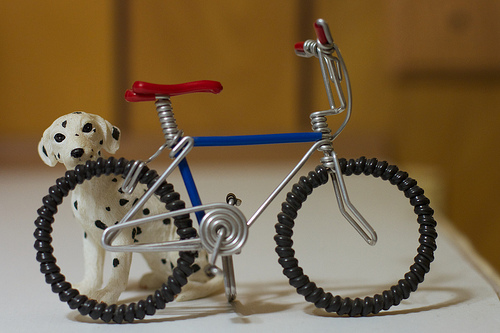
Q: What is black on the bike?
A: The wheels.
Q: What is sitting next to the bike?
A: A dalmatian.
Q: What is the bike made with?
A: Paper clips.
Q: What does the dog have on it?
A: Black spots.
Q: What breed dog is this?
A: Dalmatian.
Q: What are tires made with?
A: Phone cord.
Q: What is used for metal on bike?
A: Paper clips.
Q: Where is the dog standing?
A: Behind bike.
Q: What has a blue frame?
A: A bike.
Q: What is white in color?
A: Table.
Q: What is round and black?
A: Tires.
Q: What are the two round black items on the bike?
A: Tires.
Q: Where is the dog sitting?
A: On the table by the back wheel of the bike.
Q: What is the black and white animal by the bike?
A: A dog.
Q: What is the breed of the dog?
A: Dalmatian.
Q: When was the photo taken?
A: Daytime.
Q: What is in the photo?
A: A bike.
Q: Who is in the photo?
A: Nobody.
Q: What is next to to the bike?
A: A dog.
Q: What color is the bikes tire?
A: Black.